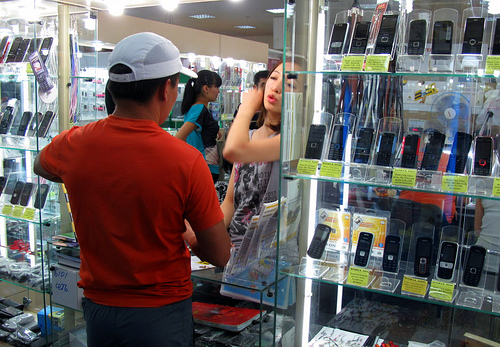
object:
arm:
[222, 108, 281, 163]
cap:
[107, 31, 198, 82]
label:
[341, 56, 365, 71]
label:
[365, 54, 390, 72]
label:
[297, 158, 319, 175]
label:
[319, 162, 343, 179]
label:
[392, 168, 418, 187]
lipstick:
[267, 94, 277, 102]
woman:
[175, 69, 223, 184]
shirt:
[228, 128, 290, 264]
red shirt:
[38, 114, 222, 308]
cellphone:
[307, 224, 331, 259]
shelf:
[1, 132, 48, 149]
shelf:
[1, 250, 54, 291]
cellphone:
[407, 19, 428, 60]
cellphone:
[328, 124, 349, 161]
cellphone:
[17, 111, 33, 136]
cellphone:
[445, 131, 473, 173]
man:
[232, 70, 271, 130]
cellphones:
[461, 245, 486, 288]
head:
[160, 76, 178, 124]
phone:
[352, 127, 375, 164]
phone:
[20, 182, 33, 205]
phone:
[434, 240, 459, 282]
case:
[21, 48, 49, 235]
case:
[295, 0, 500, 347]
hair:
[181, 70, 223, 116]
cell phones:
[326, 21, 350, 54]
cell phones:
[35, 110, 55, 137]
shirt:
[183, 103, 220, 174]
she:
[220, 56, 307, 265]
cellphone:
[461, 17, 486, 54]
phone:
[304, 124, 326, 160]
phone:
[373, 14, 400, 61]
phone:
[353, 231, 375, 268]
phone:
[472, 136, 493, 177]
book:
[192, 301, 266, 332]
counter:
[192, 259, 293, 344]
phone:
[414, 237, 434, 277]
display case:
[270, 0, 498, 346]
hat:
[107, 32, 198, 83]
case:
[284, 1, 485, 340]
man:
[33, 32, 230, 347]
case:
[262, 177, 352, 325]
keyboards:
[354, 250, 368, 269]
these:
[232, 159, 497, 340]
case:
[284, 241, 434, 347]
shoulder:
[219, 162, 235, 227]